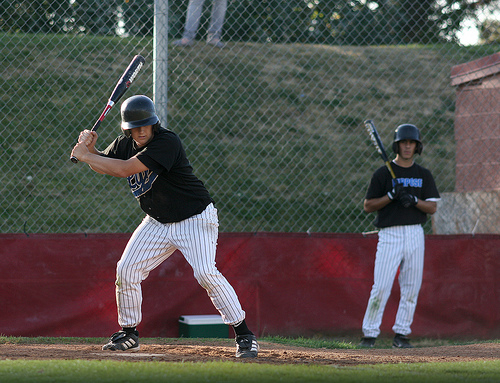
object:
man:
[68, 95, 266, 361]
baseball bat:
[66, 48, 154, 165]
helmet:
[119, 94, 162, 129]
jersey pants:
[116, 201, 245, 332]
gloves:
[388, 179, 412, 198]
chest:
[173, 308, 235, 339]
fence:
[1, 3, 282, 222]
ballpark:
[4, 0, 497, 382]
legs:
[362, 224, 401, 337]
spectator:
[358, 121, 439, 348]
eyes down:
[125, 117, 156, 137]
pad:
[91, 346, 172, 357]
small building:
[445, 51, 499, 197]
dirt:
[192, 344, 210, 357]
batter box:
[3, 341, 354, 363]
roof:
[451, 53, 499, 85]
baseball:
[4, 38, 489, 371]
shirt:
[99, 131, 217, 223]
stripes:
[118, 230, 156, 320]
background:
[303, 21, 498, 338]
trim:
[2, 227, 500, 334]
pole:
[152, 0, 168, 129]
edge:
[455, 68, 464, 195]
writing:
[395, 175, 434, 192]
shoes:
[391, 334, 414, 348]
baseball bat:
[360, 115, 412, 205]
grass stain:
[370, 292, 381, 313]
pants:
[362, 228, 426, 337]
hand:
[70, 143, 91, 159]